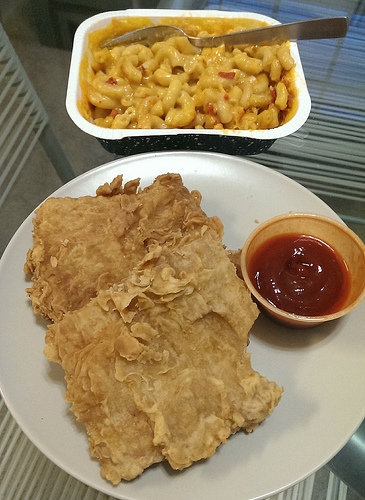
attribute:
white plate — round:
[2, 148, 362, 497]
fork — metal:
[146, 16, 360, 53]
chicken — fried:
[28, 198, 226, 371]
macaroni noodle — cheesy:
[270, 77, 290, 112]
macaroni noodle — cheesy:
[157, 74, 183, 110]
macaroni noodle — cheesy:
[83, 83, 117, 110]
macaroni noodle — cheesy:
[230, 48, 264, 76]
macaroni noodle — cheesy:
[214, 95, 234, 126]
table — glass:
[3, 2, 361, 494]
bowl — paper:
[66, 8, 311, 154]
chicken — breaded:
[159, 449, 200, 478]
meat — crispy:
[48, 259, 267, 453]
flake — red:
[216, 71, 237, 79]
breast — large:
[26, 167, 284, 485]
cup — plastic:
[216, 212, 362, 346]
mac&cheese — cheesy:
[106, 41, 284, 115]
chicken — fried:
[43, 213, 250, 436]